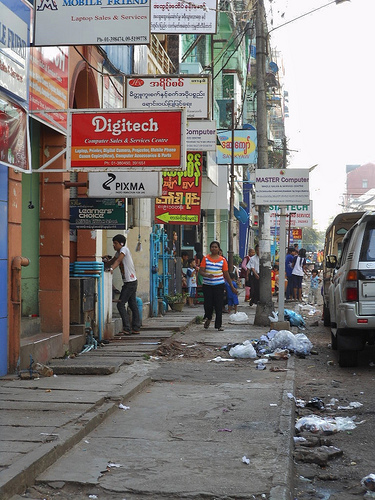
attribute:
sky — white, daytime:
[266, 0, 374, 231]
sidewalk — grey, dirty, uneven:
[1, 290, 299, 498]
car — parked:
[327, 209, 374, 371]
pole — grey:
[252, 0, 274, 325]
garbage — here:
[232, 329, 311, 360]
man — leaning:
[104, 234, 141, 335]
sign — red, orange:
[25, 109, 185, 173]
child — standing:
[306, 268, 320, 306]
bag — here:
[229, 339, 256, 360]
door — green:
[20, 121, 41, 318]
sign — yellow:
[154, 160, 199, 227]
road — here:
[297, 269, 374, 498]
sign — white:
[253, 168, 308, 208]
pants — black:
[202, 284, 224, 330]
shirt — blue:
[310, 277, 320, 287]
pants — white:
[308, 288, 319, 304]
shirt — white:
[115, 249, 137, 281]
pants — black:
[116, 281, 141, 332]